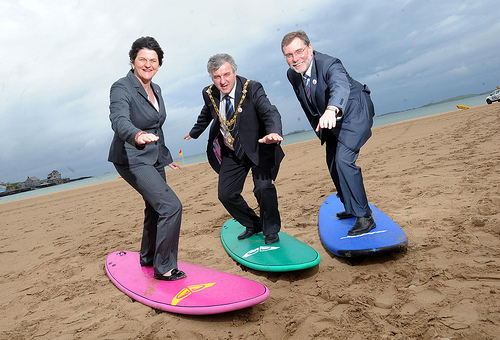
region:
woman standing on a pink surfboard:
[110, 16, 212, 312]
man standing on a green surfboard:
[190, 40, 297, 270]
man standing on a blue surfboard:
[285, 11, 398, 261]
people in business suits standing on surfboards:
[99, 17, 412, 317]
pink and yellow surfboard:
[103, 234, 241, 316]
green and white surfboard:
[221, 213, 315, 283]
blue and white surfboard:
[314, 187, 414, 272]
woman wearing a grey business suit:
[99, 18, 206, 283]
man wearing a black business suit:
[193, 36, 298, 244]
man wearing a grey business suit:
[281, 22, 385, 235]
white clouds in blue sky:
[22, 18, 122, 95]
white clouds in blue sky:
[26, 53, 85, 116]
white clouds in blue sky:
[12, 103, 72, 148]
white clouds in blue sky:
[158, 11, 227, 40]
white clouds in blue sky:
[367, 5, 499, 70]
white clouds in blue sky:
[426, 22, 471, 68]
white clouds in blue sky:
[337, 20, 389, 55]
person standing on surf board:
[93, 26, 193, 301]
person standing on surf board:
[196, 46, 276, 212]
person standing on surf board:
[287, 36, 376, 221]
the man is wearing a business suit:
[194, 80, 297, 237]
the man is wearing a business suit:
[285, 48, 376, 220]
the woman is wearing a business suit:
[107, 68, 195, 270]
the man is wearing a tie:
[222, 93, 237, 122]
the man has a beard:
[287, 53, 316, 73]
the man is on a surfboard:
[282, 31, 412, 268]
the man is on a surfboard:
[185, 48, 317, 273]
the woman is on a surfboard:
[93, 33, 260, 313]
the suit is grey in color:
[281, 48, 376, 233]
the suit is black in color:
[194, 74, 287, 235]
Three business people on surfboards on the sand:
[93, 17, 417, 308]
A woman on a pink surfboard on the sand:
[51, 7, 199, 326]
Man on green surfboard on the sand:
[191, 36, 326, 276]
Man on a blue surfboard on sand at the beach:
[280, 5, 420, 276]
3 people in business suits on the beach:
[81, 24, 491, 213]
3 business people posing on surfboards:
[85, 18, 384, 289]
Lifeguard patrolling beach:
[390, 6, 499, 194]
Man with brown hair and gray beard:
[279, 23, 328, 94]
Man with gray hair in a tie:
[201, 40, 251, 110]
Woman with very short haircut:
[90, 13, 174, 88]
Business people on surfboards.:
[68, 21, 423, 301]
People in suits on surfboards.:
[74, 27, 458, 334]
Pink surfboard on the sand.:
[96, 232, 271, 333]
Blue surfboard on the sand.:
[301, 149, 440, 299]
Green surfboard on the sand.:
[203, 181, 351, 293]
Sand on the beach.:
[29, 160, 126, 273]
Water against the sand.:
[28, 151, 93, 229]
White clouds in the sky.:
[25, 34, 97, 129]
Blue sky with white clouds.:
[358, 24, 470, 120]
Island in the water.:
[1, 165, 120, 222]